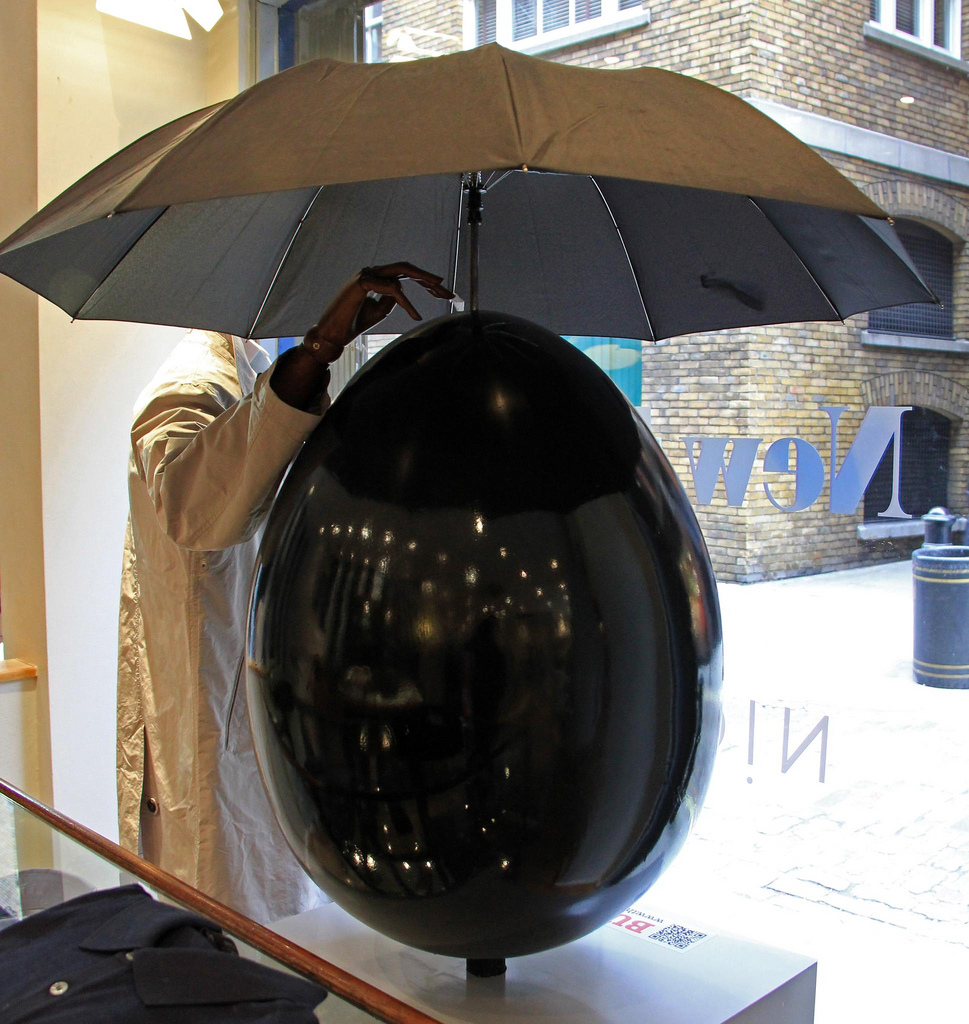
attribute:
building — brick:
[362, 3, 932, 582]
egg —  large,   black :
[264, 346, 688, 959]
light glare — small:
[388, 849, 424, 882]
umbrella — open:
[5, 27, 961, 395]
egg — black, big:
[203, 277, 766, 985]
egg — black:
[222, 301, 778, 961]